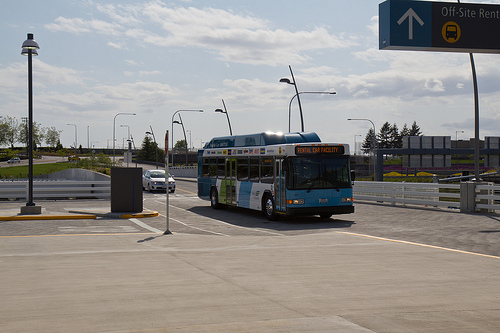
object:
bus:
[197, 131, 356, 221]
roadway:
[0, 179, 500, 258]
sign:
[378, 0, 500, 53]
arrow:
[397, 8, 425, 41]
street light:
[21, 33, 40, 56]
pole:
[26, 49, 35, 206]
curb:
[1, 212, 160, 222]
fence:
[0, 179, 111, 201]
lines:
[128, 218, 162, 233]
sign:
[163, 130, 173, 235]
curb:
[0, 232, 348, 239]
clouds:
[0, 1, 500, 148]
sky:
[1, 0, 500, 155]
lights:
[67, 64, 335, 169]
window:
[287, 156, 352, 190]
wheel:
[263, 195, 277, 220]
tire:
[211, 189, 228, 209]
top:
[203, 132, 322, 149]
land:
[1, 154, 500, 333]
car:
[142, 169, 176, 193]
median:
[0, 208, 158, 220]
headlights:
[287, 197, 354, 204]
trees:
[361, 121, 424, 160]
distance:
[0, 86, 500, 158]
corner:
[167, 235, 359, 256]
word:
[165, 140, 167, 149]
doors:
[275, 159, 289, 213]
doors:
[226, 157, 238, 206]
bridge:
[47, 165, 199, 198]